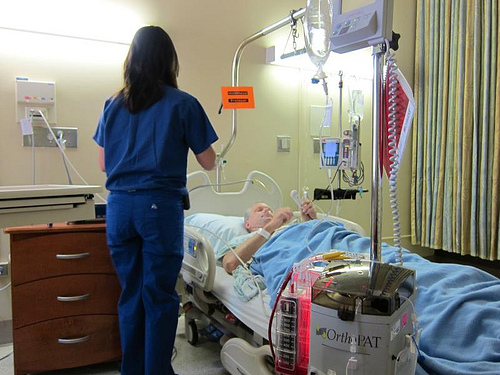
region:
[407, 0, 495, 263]
a set of striped curtains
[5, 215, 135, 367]
a set of drawers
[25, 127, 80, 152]
an electrical outlet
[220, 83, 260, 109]
a bright orange sign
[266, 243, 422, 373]
a large piece of medical equipment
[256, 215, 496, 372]
a pale blue blanket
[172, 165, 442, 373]
a white hospital bed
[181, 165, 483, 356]
a man laying in a hospital bed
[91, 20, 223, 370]
a woman in blue scrubs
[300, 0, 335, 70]
a bag of fluids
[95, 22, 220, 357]
a woman wearing blue scrubs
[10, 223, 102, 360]
a brown cabinet with metal handles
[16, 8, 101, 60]
white wall of the hospital room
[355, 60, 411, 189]
red folder hanging from a pole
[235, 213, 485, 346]
blue blanket draped over the man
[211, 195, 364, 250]
a man lying in a hospital bed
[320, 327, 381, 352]
black lettering on a white cardboard box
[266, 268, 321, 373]
a red plastic urine collection machine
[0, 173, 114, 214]
a white tray attached to the wall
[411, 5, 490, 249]
yellow and blue curtains over the window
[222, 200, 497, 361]
man laying in a hospital bed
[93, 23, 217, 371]
nurse in blue next to the bed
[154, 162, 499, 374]
white hospital bed in the room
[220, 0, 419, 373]
IV machine next to the bed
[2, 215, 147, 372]
brown dresser next to the bed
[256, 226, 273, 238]
white medical bracelet on the patient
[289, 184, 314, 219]
heart rate monitor in the patients hand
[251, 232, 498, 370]
light blue blanket on the patient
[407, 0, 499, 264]
curtains covering the windows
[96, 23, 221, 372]
nurse checking on her patient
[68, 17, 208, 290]
this is a lady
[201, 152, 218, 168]
the lady is light skinned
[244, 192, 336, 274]
this is a man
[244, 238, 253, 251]
the man is light skinned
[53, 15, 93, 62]
this is the wall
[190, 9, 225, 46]
the wall is white in color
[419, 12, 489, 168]
this is a curtain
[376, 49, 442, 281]
this is a cable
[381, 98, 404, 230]
the cable is white in color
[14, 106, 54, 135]
this is the socket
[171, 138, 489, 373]
The hospital bed is in use.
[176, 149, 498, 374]
The hospital bed is occupied.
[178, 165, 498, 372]
The man is lying in a hospital bed.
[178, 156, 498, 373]
A blue blanket is covering the man..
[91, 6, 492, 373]
A woman is standing beside the bed.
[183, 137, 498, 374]
The man is holding a controller.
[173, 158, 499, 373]
The headboard on bed is white.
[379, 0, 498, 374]
The curtain striped.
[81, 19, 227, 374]
The woman has dark hair.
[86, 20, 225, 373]
The woman is wearing a blue uniform.